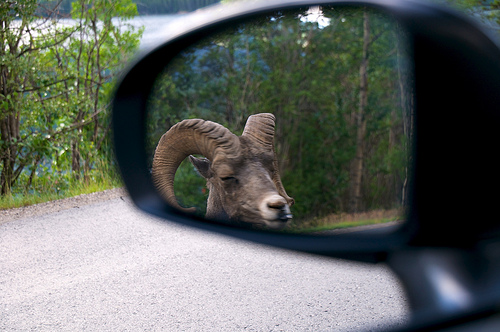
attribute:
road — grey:
[0, 185, 413, 329]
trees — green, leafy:
[1, 0, 142, 194]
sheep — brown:
[150, 101, 333, 235]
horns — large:
[146, 100, 322, 179]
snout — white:
[234, 174, 311, 232]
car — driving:
[130, 23, 485, 323]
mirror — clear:
[279, 45, 389, 212]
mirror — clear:
[278, 31, 396, 211]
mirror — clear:
[290, 55, 399, 196]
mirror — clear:
[242, 55, 437, 221]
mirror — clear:
[260, 49, 369, 178]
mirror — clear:
[230, 66, 339, 123]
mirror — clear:
[340, 130, 381, 202]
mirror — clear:
[173, 105, 233, 146]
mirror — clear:
[258, 38, 326, 86]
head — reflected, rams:
[138, 94, 335, 238]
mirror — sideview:
[88, 22, 469, 276]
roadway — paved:
[59, 244, 174, 315]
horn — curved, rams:
[150, 113, 230, 191]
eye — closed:
[209, 168, 240, 195]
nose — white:
[240, 174, 318, 240]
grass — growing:
[23, 161, 104, 223]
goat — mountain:
[148, 95, 346, 245]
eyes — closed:
[210, 149, 304, 192]